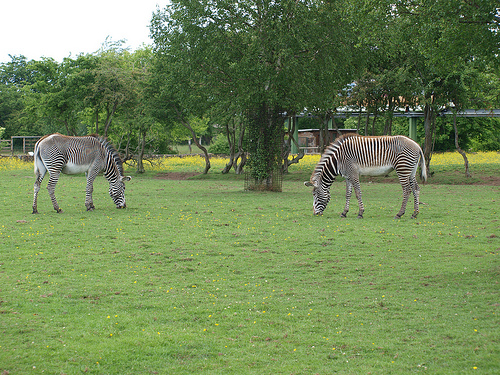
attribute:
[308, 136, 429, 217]
zebra — black, white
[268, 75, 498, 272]
zebra — white, black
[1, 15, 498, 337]
background — with animals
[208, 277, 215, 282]
flower — yellow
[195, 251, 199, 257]
flower — yellow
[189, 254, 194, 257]
flower — yellow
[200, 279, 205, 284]
flower — yellow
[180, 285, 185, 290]
flower — yellow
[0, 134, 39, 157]
fence — small, brown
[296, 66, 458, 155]
shelter — above zebra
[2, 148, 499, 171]
dandelions — yellow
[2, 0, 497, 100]
sky — sunny, white, clear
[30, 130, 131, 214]
zebra — white, black, standing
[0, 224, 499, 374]
field — green, enclosed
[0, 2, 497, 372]
park — with animals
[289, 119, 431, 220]
zebra — black, white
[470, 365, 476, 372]
flowers — yellow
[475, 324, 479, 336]
flowers — yellow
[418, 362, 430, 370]
flowers — yellow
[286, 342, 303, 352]
flowers — yellow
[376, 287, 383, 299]
flowers — yellow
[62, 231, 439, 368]
grass — green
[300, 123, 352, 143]
fence — wooden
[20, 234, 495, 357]
grass — green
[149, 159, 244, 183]
field — open